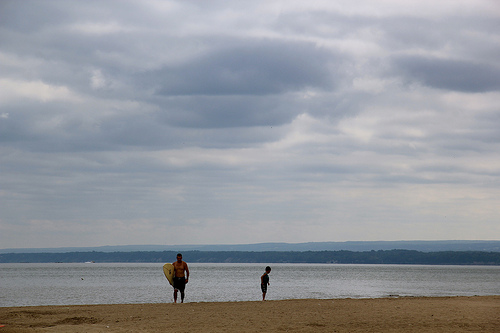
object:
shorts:
[168, 280, 188, 295]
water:
[322, 265, 330, 278]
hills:
[392, 240, 460, 262]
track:
[305, 320, 327, 327]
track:
[277, 324, 299, 329]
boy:
[259, 265, 270, 301]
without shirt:
[172, 262, 184, 276]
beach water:
[371, 278, 463, 302]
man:
[163, 255, 190, 304]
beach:
[215, 303, 288, 309]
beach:
[414, 313, 453, 330]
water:
[465, 289, 491, 302]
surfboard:
[162, 263, 175, 283]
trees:
[487, 248, 498, 265]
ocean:
[1, 264, 58, 305]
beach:
[0, 300, 49, 330]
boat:
[80, 257, 97, 267]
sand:
[340, 323, 350, 330]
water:
[465, 278, 494, 289]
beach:
[117, 318, 155, 329]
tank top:
[167, 253, 191, 285]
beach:
[465, 308, 497, 329]